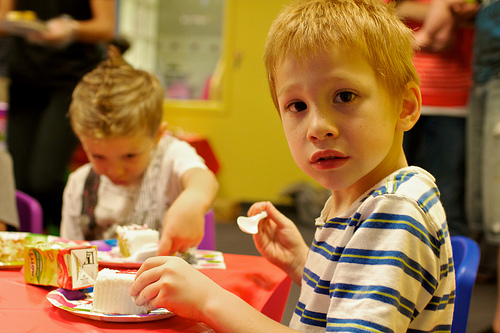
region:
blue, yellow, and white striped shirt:
[318, 216, 448, 331]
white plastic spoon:
[236, 210, 272, 233]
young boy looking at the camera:
[273, 0, 410, 188]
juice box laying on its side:
[25, 244, 94, 291]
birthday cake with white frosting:
[94, 221, 170, 321]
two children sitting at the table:
[62, 37, 417, 329]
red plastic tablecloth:
[226, 256, 271, 290]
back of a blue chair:
[451, 235, 481, 332]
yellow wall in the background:
[221, 105, 275, 183]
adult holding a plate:
[5, 2, 71, 155]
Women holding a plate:
[0, 0, 133, 52]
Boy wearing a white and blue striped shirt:
[224, 1, 479, 332]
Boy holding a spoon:
[217, 0, 467, 332]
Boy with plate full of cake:
[28, 36, 223, 263]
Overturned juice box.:
[15, 232, 100, 287]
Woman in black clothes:
[0, 0, 130, 233]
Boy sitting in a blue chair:
[215, 0, 480, 330]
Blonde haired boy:
[220, 0, 478, 330]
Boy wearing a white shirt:
[40, 42, 225, 254]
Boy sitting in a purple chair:
[44, 36, 219, 256]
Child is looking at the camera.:
[231, 0, 450, 322]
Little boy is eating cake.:
[74, 263, 175, 322]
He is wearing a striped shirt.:
[308, 217, 441, 329]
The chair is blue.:
[426, 214, 478, 328]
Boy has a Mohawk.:
[77, 45, 165, 140]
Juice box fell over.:
[13, 240, 89, 296]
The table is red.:
[5, 275, 74, 331]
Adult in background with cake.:
[13, 7, 116, 204]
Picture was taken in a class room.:
[6, 11, 499, 318]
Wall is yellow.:
[221, 50, 273, 175]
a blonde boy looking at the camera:
[220, 17, 416, 330]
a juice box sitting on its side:
[12, 244, 91, 288]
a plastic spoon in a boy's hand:
[217, 180, 290, 236]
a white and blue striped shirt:
[262, 190, 472, 331]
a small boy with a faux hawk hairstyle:
[61, 54, 238, 255]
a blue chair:
[412, 217, 490, 331]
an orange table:
[5, 229, 304, 326]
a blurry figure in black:
[2, 2, 109, 229]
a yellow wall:
[110, 2, 388, 213]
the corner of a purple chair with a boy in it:
[197, 208, 222, 254]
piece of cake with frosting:
[90, 260, 171, 331]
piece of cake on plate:
[56, 227, 214, 267]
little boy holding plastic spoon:
[212, 192, 306, 272]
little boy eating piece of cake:
[51, 7, 471, 332]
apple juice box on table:
[15, 233, 121, 303]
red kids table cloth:
[0, 250, 300, 332]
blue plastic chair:
[432, 210, 498, 325]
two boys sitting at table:
[67, 3, 498, 331]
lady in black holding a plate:
[0, 1, 142, 233]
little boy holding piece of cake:
[83, 223, 220, 331]